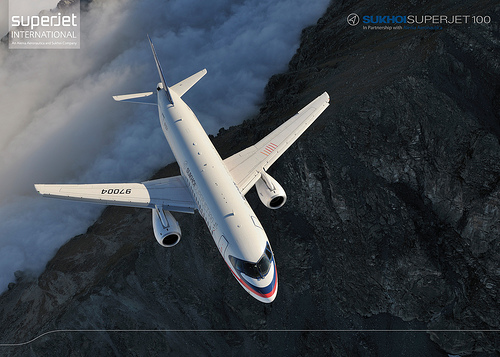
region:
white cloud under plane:
[0, 1, 325, 275]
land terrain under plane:
[9, 6, 494, 351]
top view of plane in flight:
[31, 32, 334, 304]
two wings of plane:
[32, 91, 335, 216]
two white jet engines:
[135, 168, 286, 248]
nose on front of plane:
[227, 240, 282, 307]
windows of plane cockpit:
[228, 239, 273, 281]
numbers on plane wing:
[31, 174, 184, 206]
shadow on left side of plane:
[157, 84, 283, 303]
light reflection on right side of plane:
[155, 64, 280, 303]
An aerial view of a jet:
[1, 0, 498, 355]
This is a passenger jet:
[31, 30, 332, 305]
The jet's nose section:
[226, 241, 281, 303]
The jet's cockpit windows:
[228, 240, 273, 280]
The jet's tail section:
[111, 31, 208, 106]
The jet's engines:
[151, 170, 288, 250]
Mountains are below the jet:
[0, 0, 497, 352]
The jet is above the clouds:
[1, 0, 333, 303]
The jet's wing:
[31, 174, 198, 214]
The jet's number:
[99, 185, 133, 195]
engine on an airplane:
[250, 165, 290, 214]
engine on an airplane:
[144, 199, 184, 253]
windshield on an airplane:
[225, 239, 274, 279]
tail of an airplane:
[100, 35, 217, 117]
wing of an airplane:
[28, 162, 195, 219]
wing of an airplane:
[222, 85, 341, 212]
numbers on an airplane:
[95, 185, 137, 197]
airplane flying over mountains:
[17, 29, 343, 314]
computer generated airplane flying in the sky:
[23, 26, 340, 309]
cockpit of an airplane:
[222, 230, 284, 303]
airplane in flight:
[11, 37, 350, 308]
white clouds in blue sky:
[20, 68, 78, 110]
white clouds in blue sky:
[309, 244, 359, 288]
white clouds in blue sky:
[366, 248, 439, 314]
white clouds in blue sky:
[386, 69, 450, 133]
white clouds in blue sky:
[297, 16, 357, 46]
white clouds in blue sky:
[209, 28, 266, 58]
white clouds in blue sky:
[52, 296, 160, 329]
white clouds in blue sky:
[98, 243, 148, 294]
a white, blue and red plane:
[40, 32, 332, 304]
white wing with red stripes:
[223, 89, 331, 198]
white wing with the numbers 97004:
[33, 174, 201, 214]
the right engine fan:
[256, 166, 288, 211]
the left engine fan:
[149, 199, 184, 246]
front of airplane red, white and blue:
[224, 237, 281, 305]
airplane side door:
[214, 233, 230, 260]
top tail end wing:
[143, 29, 176, 105]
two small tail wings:
[111, 64, 211, 106]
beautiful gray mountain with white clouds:
[2, 4, 499, 351]